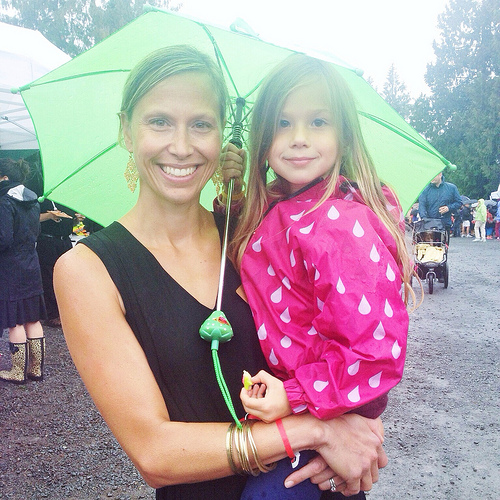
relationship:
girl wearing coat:
[232, 44, 415, 498] [205, 167, 407, 425]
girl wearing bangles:
[53, 44, 387, 500] [247, 419, 277, 473]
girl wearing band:
[53, 44, 387, 500] [276, 418, 296, 462]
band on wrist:
[276, 418, 296, 462] [301, 409, 335, 455]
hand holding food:
[238, 367, 290, 428] [242, 370, 254, 394]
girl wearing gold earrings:
[53, 44, 387, 500] [121, 150, 142, 193]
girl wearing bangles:
[232, 44, 415, 498] [228, 412, 273, 480]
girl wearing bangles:
[50, 42, 390, 495] [228, 412, 273, 480]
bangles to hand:
[226, 420, 263, 481] [302, 411, 387, 498]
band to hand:
[269, 413, 301, 460] [249, 385, 391, 499]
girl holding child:
[53, 44, 387, 500] [217, 44, 422, 419]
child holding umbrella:
[225, 58, 369, 494] [32, 6, 439, 251]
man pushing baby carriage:
[419, 171, 462, 284] [410, 214, 449, 294]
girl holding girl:
[53, 44, 387, 500] [241, 40, 427, 498]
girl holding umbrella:
[232, 44, 415, 498] [7, 22, 477, 266]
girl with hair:
[232, 44, 415, 498] [225, 55, 423, 312]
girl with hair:
[232, 44, 415, 498] [244, 67, 374, 212]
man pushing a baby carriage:
[419, 171, 462, 284] [410, 220, 448, 295]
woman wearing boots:
[0, 156, 52, 393] [1, 334, 51, 387]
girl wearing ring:
[53, 44, 387, 500] [329, 478, 337, 492]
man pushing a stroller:
[404, 163, 467, 299] [409, 217, 451, 294]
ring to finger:
[347, 476, 381, 497] [320, 473, 341, 496]